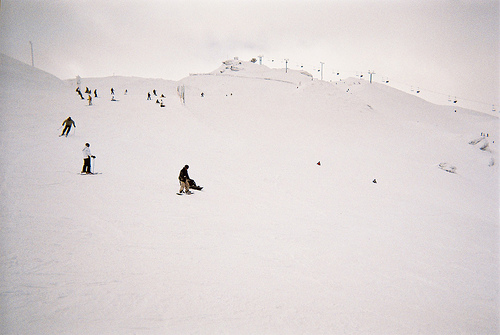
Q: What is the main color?
A: White.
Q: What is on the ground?
A: Snow.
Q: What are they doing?
A: Skiing.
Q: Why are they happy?
A: Having fun.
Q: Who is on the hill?
A: People.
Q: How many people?
A: 15.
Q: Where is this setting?
A: A ski resort.